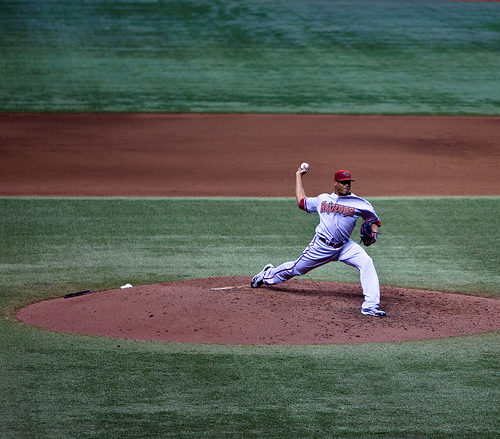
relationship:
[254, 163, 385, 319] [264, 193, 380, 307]
baseball player in uniform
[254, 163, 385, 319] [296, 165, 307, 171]
baseball player has hand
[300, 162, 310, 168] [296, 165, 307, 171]
ball in hand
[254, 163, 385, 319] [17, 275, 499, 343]
baseball player on mound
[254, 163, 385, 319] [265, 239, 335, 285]
baseball player has leg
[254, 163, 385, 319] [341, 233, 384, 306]
baseball player has leg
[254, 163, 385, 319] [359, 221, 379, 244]
baseball player has hand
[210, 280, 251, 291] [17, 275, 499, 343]
line on mound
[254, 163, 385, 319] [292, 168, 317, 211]
baseball player has arm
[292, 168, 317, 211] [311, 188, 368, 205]
arm behind back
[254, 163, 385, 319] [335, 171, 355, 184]
baseball player wearing cap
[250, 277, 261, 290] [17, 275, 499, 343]
toe into mound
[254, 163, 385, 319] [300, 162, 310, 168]
baseball player throwing ball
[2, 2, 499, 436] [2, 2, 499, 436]
grass in grass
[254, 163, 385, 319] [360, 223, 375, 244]
baseball player has glove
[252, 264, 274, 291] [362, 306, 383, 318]
cleat next to cleat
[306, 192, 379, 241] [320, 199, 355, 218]
shirt has letters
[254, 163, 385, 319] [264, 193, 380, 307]
baseball player wearing uniform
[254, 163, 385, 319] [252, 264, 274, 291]
baseball player wearing cleat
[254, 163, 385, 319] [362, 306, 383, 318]
baseball player wearing cleat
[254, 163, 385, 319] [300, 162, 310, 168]
baseball player holding ball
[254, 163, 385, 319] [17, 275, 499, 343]
baseball player standing on mound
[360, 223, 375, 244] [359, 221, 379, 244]
glove in hand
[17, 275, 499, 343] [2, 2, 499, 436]
mound in middle of grass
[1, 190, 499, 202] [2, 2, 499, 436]
line on grass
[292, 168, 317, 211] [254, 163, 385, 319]
arm of baseball player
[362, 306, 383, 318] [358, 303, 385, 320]
cleat on foot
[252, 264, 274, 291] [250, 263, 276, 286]
cleat on foot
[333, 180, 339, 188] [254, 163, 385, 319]
ear of baseball player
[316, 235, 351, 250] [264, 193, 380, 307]
belt on uniform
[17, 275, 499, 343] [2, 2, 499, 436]
mound on grass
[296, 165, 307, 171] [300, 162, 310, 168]
hand holding ball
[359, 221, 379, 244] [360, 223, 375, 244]
hand holding glove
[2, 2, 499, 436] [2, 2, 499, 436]
grass on grass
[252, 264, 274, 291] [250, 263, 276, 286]
cleat covering foot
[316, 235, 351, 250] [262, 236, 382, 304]
belt holding up pants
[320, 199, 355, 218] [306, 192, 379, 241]
letters on jersey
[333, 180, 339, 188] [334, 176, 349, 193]
ear on head